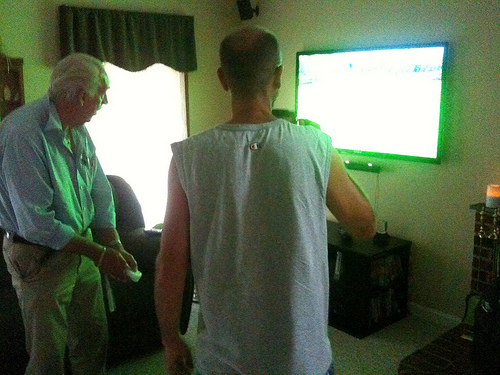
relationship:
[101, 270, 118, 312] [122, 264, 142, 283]
strap attached to controller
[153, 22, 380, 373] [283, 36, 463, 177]
man watching t.v.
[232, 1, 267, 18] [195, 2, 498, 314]
black speaker mounted on wall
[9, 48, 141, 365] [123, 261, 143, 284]
man holding remote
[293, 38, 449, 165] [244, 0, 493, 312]
t.v. mounted on wall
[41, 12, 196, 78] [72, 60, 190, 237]
curtain on window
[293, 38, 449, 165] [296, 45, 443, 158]
t.v. has screen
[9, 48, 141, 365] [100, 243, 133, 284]
man has hand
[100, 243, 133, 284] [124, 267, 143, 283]
hand holding remote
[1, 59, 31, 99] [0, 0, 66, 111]
shelf attached to wall